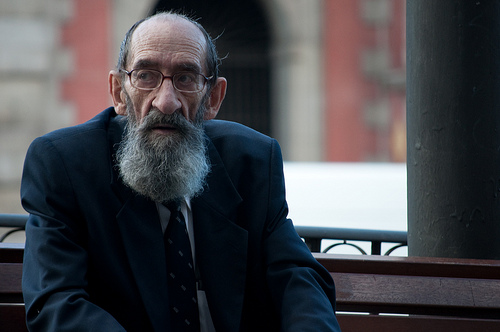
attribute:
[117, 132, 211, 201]
beard — long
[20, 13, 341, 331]
man — old, balding, older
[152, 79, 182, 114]
nose — large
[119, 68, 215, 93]
eyeglasses — a pair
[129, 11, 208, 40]
hair line — receding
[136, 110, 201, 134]
moustache — scruffy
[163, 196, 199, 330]
necktie — black, blue, patterned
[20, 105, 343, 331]
suit — black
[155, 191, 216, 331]
shirt — white, dress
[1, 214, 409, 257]
railing — iron, top, long, metal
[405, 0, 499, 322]
support post — concrete, large, grey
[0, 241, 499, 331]
bench — wooden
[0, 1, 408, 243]
building — red, brick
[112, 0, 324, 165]
entryway — stone, an arch